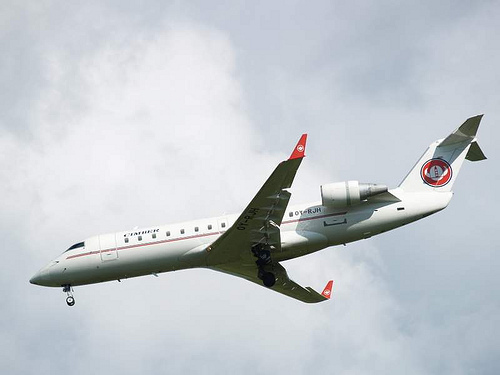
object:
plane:
[30, 116, 485, 307]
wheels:
[263, 272, 275, 286]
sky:
[0, 0, 495, 372]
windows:
[180, 229, 184, 234]